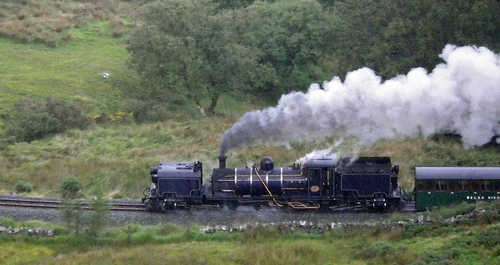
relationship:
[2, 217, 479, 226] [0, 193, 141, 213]
fence running length of train tracks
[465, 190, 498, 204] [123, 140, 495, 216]
letters on train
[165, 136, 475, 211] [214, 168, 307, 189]
train banded by banding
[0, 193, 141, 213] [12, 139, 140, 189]
train tracks spliced through pasture fields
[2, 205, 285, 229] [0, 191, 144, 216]
gravel surrounding train tracks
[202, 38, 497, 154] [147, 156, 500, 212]
smoke coming from train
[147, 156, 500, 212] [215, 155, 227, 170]
train coming from stack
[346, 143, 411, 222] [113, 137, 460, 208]
bin on train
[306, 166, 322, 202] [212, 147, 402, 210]
door on engine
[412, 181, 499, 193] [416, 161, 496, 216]
windows on train car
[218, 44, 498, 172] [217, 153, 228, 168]
steam escaping stack